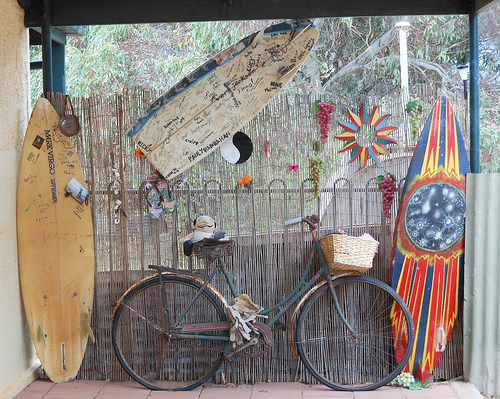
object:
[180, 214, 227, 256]
doll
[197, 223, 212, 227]
mustache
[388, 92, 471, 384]
board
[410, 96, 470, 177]
stripes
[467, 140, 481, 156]
ground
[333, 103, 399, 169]
plaque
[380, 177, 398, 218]
grapes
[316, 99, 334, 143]
grape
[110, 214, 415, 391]
bicycle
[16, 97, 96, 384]
board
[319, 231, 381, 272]
basket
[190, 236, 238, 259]
bicycle seat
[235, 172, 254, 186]
orange flower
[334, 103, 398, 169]
sun pattern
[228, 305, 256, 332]
gloves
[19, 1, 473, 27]
ceiling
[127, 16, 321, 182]
surfboard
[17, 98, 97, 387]
tan wood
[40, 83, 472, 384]
fence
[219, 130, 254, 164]
round disk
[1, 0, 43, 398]
wall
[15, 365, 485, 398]
ground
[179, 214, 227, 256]
toy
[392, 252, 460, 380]
stripes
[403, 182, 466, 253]
circle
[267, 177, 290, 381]
pipes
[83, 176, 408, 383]
railing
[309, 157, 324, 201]
bunch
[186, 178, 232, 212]
signatures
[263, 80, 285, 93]
writing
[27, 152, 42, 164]
writing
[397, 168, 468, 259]
pattern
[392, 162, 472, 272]
middle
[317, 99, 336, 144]
bunch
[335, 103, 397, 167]
points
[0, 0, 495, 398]
balcony